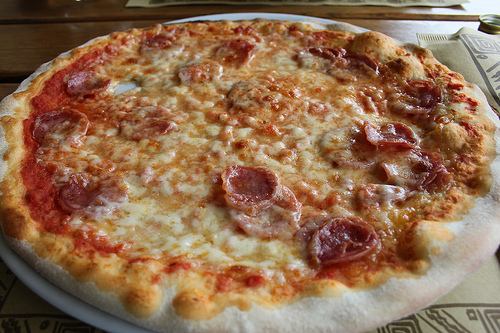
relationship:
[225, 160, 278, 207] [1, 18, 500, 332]
pepperoni on a pizza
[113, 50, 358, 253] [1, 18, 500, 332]
melted cheese on pizza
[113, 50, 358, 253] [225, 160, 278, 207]
melted cheese and pepperoni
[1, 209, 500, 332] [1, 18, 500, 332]
crust on a pizza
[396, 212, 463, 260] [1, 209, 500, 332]
air pocket in crust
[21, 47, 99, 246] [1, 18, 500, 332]
sauce for pizza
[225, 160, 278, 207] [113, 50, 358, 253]
pepperoni covered in melted cheese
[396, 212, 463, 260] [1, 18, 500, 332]
air pocket on pizza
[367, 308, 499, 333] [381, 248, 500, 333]
design on box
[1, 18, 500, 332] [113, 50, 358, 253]
pizza with melted cheese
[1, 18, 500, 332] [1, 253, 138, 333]
pizza on a plate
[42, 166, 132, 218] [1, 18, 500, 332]
ham on pizza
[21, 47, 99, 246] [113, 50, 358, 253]
sauce and melted cheese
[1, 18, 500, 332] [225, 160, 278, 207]
pizza topped with pepperoni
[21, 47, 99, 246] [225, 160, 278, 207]
sauce and pepperoni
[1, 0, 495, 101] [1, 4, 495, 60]
table has slats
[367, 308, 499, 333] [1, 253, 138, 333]
design under plate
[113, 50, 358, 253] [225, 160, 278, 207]
melted cheese with pepperoni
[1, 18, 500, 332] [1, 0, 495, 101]
pizza on a table